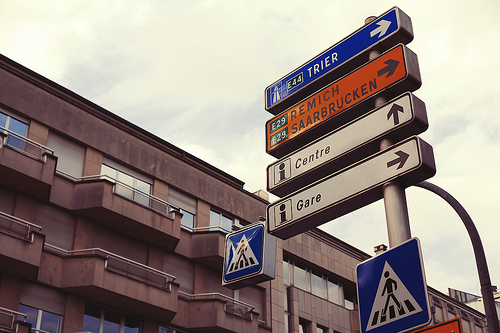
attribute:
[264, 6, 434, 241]
street signs — stacked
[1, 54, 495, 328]
building — brown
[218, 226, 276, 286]
sign — blue, square, blue/ white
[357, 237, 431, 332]
sign — blue, square, blue/ white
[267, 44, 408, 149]
sign — orange, red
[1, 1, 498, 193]
sky — cloudy, blue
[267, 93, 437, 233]
signs — white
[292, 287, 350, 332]
tile — brown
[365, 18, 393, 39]
arrow — white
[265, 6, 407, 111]
sign — blue, blue/ white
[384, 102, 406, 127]
arrow — black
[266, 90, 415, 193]
sign — white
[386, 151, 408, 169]
arrow — black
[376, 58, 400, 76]
arrow — black